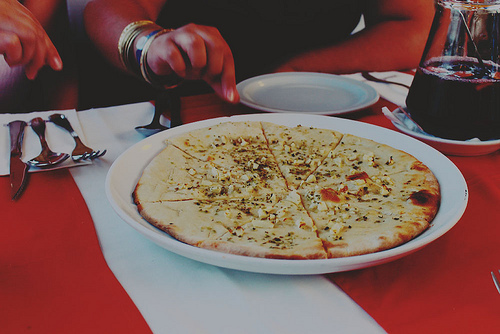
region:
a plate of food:
[103, 102, 475, 289]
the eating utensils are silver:
[4, 107, 109, 207]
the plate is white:
[214, 50, 385, 146]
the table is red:
[8, 85, 498, 330]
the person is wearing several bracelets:
[86, 5, 253, 110]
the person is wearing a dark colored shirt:
[146, 0, 408, 95]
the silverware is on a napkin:
[1, 105, 106, 208]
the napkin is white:
[0, 107, 100, 177]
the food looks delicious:
[114, 105, 466, 277]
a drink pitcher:
[391, 0, 498, 147]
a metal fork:
[45, 107, 114, 162]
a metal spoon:
[22, 107, 72, 172]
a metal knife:
[3, 112, 33, 211]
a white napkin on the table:
[0, 102, 97, 179]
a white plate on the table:
[102, 105, 472, 278]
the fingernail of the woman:
[222, 81, 241, 103]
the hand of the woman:
[135, 18, 248, 107]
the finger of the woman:
[153, 33, 188, 79]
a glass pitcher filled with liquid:
[398, 0, 498, 144]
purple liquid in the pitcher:
[403, 55, 498, 142]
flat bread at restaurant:
[11, 7, 460, 308]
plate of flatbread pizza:
[95, 102, 470, 311]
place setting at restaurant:
[7, 95, 137, 242]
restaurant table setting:
[3, 52, 410, 316]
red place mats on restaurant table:
[9, 92, 491, 328]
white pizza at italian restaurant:
[9, 32, 452, 324]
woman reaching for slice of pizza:
[100, 24, 377, 326]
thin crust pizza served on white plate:
[103, 106, 455, 309]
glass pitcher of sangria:
[389, 0, 499, 170]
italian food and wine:
[90, 3, 499, 309]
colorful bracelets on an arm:
[69, 0, 245, 111]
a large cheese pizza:
[129, 114, 449, 274]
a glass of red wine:
[392, 10, 494, 157]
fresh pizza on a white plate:
[89, 102, 478, 280]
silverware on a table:
[6, 102, 113, 207]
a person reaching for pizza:
[74, 7, 479, 291]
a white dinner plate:
[222, 59, 385, 124]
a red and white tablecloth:
[1, 90, 495, 332]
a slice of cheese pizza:
[298, 159, 453, 260]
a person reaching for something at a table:
[74, 8, 491, 115]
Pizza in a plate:
[98, 100, 483, 281]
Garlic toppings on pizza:
[147, 110, 412, 260]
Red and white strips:
[0, 170, 495, 320]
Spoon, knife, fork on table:
[5, 110, 105, 220]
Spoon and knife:
[125, 82, 202, 142]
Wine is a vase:
[395, 43, 491, 149]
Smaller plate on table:
[228, 50, 389, 133]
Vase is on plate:
[371, 70, 497, 170]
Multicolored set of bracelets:
[90, 7, 203, 87]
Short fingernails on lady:
[176, 58, 303, 120]